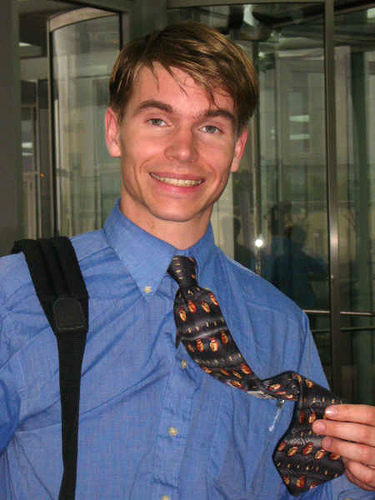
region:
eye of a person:
[144, 109, 173, 130]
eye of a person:
[197, 119, 224, 135]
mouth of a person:
[141, 160, 212, 192]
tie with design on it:
[163, 244, 354, 498]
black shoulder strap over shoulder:
[2, 224, 94, 498]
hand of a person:
[309, 396, 374, 498]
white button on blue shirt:
[163, 423, 182, 442]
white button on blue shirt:
[159, 492, 172, 498]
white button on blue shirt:
[179, 356, 190, 371]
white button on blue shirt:
[141, 282, 152, 295]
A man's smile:
[147, 170, 210, 193]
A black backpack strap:
[13, 233, 92, 380]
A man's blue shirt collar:
[99, 196, 221, 304]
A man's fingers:
[312, 402, 374, 488]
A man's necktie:
[165, 253, 297, 402]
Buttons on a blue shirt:
[159, 353, 190, 496]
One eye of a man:
[139, 111, 172, 131]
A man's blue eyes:
[140, 111, 223, 137]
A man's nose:
[162, 128, 197, 161]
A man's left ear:
[103, 107, 122, 159]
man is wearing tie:
[159, 256, 359, 495]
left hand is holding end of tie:
[309, 391, 373, 494]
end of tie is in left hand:
[270, 371, 351, 496]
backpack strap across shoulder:
[4, 236, 89, 499]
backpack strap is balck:
[7, 236, 90, 499]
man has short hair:
[98, 10, 256, 127]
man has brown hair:
[89, 15, 263, 129]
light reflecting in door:
[252, 234, 265, 249]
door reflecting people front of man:
[237, 51, 374, 410]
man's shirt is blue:
[0, 195, 372, 498]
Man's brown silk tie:
[175, 248, 325, 498]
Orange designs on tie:
[276, 442, 337, 462]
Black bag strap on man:
[10, 227, 96, 497]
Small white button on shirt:
[167, 420, 183, 435]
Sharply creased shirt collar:
[104, 213, 217, 302]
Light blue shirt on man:
[7, 208, 355, 499]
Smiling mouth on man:
[153, 164, 207, 191]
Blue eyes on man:
[144, 107, 230, 134]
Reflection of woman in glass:
[282, 220, 329, 309]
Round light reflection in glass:
[250, 235, 266, 249]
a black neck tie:
[167, 255, 345, 496]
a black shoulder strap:
[12, 235, 89, 498]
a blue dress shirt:
[88, 196, 311, 498]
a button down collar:
[104, 204, 174, 304]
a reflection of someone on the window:
[270, 223, 330, 318]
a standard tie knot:
[167, 254, 198, 285]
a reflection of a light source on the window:
[251, 233, 267, 249]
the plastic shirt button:
[143, 282, 152, 294]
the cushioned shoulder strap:
[12, 233, 89, 334]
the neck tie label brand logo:
[245, 389, 273, 400]